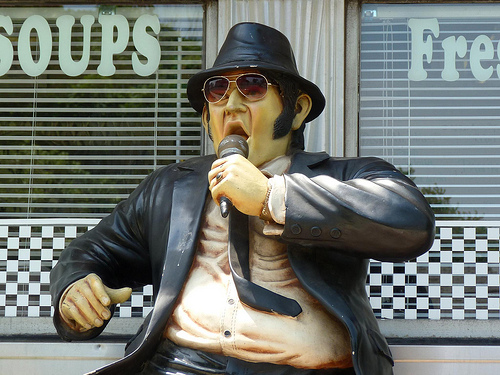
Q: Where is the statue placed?
A: Outside of a restaurant.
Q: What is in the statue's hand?
A: Microphone.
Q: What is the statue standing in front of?
A: A restaurant.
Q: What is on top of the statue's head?
A: Black hat.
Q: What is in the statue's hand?
A: Microphone.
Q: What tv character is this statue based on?
A: Blues brother.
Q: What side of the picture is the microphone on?
A: Right.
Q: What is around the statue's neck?
A: Black tie.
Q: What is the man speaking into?
A: Microphone.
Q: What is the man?
A: Statue.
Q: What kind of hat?
A: Fedora.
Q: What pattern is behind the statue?
A: Checkered.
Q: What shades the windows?
A: Blinds.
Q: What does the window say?
A: Soups.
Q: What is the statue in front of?
A: Restaurant.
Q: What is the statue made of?
A: Plastic.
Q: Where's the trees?
A: Reflected in window.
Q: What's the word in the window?
A: SOUPS.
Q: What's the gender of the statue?
A: Male.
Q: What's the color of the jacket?
A: Black.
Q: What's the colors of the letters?
A: White.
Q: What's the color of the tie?
A: Black.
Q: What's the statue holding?
A: Microphone.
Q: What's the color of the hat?
A: Black.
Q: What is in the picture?
A: A statue is in the picture.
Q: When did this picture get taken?
A: It was taken in the day time.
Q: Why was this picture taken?
A: To show the statue.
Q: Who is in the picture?
A: Nobody is in the picture.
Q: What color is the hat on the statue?
A: The hat is black.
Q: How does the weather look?
A: The weather looks nice and sunny.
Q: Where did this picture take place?
A: It took place in front of a store.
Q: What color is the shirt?
A: The shirt is white.